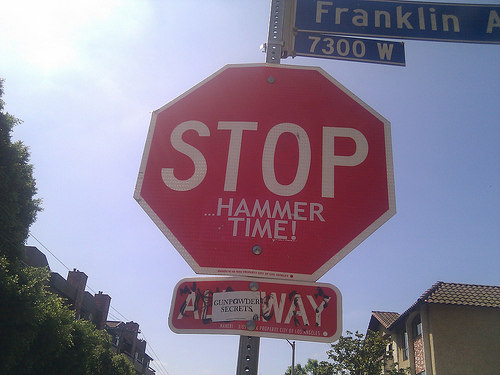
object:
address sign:
[266, 0, 500, 65]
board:
[130, 60, 396, 282]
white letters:
[216, 194, 327, 241]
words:
[216, 197, 325, 240]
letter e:
[294, 202, 308, 221]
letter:
[216, 198, 234, 217]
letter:
[217, 121, 261, 193]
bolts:
[251, 76, 276, 255]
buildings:
[361, 280, 498, 375]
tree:
[277, 322, 399, 375]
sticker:
[212, 291, 261, 322]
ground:
[409, 185, 454, 228]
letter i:
[244, 218, 250, 237]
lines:
[22, 227, 165, 375]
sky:
[0, 0, 500, 375]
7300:
[308, 35, 366, 57]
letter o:
[262, 122, 312, 198]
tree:
[0, 76, 145, 375]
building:
[18, 246, 159, 375]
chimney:
[65, 267, 88, 288]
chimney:
[94, 291, 112, 329]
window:
[79, 310, 86, 321]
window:
[61, 296, 74, 310]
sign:
[129, 61, 399, 278]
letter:
[321, 127, 370, 199]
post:
[233, 332, 263, 375]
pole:
[237, 0, 292, 375]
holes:
[238, 332, 260, 375]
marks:
[164, 276, 344, 345]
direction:
[376, 41, 394, 61]